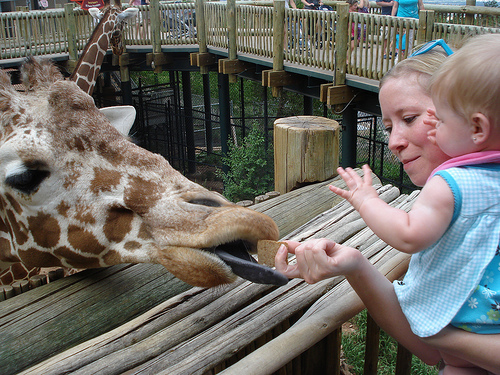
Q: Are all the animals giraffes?
A: Yes, all the animals are giraffes.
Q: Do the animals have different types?
A: No, all the animals are giraffes.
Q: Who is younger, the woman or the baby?
A: The baby is younger than the woman.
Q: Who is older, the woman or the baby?
A: The woman is older than the baby.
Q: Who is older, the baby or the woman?
A: The woman is older than the baby.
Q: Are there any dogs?
A: No, there are no dogs.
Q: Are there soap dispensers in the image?
A: No, there are no soap dispensers.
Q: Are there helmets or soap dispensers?
A: No, there are no soap dispensers or helmets.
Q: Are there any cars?
A: No, there are no cars.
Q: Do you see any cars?
A: No, there are no cars.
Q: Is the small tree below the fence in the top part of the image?
A: Yes, the tree is below the fence.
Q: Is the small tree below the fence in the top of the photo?
A: Yes, the tree is below the fence.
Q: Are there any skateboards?
A: No, there are no skateboards.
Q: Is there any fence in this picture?
A: Yes, there is a fence.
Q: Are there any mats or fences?
A: Yes, there is a fence.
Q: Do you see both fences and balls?
A: No, there is a fence but no balls.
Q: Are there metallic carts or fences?
A: Yes, there is a metal fence.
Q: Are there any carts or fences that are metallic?
A: Yes, the fence is metallic.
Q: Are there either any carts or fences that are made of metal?
A: Yes, the fence is made of metal.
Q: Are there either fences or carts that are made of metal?
A: Yes, the fence is made of metal.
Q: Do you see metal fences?
A: Yes, there is a fence that is made of metal.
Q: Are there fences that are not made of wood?
A: Yes, there is a fence that is made of metal.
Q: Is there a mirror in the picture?
A: No, there are no mirrors.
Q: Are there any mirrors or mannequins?
A: No, there are no mirrors or mannequins.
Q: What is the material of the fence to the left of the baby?
A: The fence is made of metal.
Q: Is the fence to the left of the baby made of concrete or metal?
A: The fence is made of metal.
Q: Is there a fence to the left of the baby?
A: Yes, there is a fence to the left of the baby.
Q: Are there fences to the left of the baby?
A: Yes, there is a fence to the left of the baby.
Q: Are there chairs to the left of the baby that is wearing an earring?
A: No, there is a fence to the left of the baby.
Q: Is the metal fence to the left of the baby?
A: Yes, the fence is to the left of the baby.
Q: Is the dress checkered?
A: Yes, the dress is checkered.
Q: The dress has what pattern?
A: The dress is checkered.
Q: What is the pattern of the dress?
A: The dress is checkered.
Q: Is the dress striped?
A: No, the dress is checkered.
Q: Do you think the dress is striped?
A: No, the dress is checkered.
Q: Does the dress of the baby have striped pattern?
A: No, the dress is checkered.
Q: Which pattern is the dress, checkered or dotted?
A: The dress is checkered.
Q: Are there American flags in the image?
A: No, there are no American flags.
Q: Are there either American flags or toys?
A: No, there are no American flags or toys.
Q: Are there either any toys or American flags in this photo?
A: No, there are no American flags or toys.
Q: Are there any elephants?
A: No, there are no elephants.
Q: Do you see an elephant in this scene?
A: No, there are no elephants.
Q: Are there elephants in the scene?
A: No, there are no elephants.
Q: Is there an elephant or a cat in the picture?
A: No, there are no elephants or cats.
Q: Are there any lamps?
A: No, there are no lamps.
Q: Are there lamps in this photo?
A: No, there are no lamps.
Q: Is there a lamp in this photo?
A: No, there are no lamps.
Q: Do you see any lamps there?
A: No, there are no lamps.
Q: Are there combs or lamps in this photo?
A: No, there are no lamps or combs.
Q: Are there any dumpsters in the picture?
A: No, there are no dumpsters.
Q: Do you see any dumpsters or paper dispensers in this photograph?
A: No, there are no dumpsters or paper dispensers.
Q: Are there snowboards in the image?
A: No, there are no snowboards.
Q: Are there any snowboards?
A: No, there are no snowboards.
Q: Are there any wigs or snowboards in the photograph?
A: No, there are no snowboards or wigs.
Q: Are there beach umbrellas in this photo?
A: No, there are no beach umbrellas.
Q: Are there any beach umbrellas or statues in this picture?
A: No, there are no beach umbrellas or statues.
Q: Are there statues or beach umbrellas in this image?
A: No, there are no beach umbrellas or statues.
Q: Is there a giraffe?
A: Yes, there are giraffes.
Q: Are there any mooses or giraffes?
A: Yes, there are giraffes.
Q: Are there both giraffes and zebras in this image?
A: No, there are giraffes but no zebras.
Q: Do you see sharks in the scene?
A: No, there are no sharks.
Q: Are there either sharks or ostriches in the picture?
A: No, there are no sharks or ostriches.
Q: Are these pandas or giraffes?
A: These are giraffes.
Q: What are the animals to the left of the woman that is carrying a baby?
A: The animals are giraffes.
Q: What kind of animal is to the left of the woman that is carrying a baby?
A: The animals are giraffes.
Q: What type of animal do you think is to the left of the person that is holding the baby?
A: The animals are giraffes.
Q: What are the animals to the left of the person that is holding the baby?
A: The animals are giraffes.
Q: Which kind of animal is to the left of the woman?
A: The animals are giraffes.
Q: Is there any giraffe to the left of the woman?
A: Yes, there are giraffes to the left of the woman.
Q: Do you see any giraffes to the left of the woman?
A: Yes, there are giraffes to the left of the woman.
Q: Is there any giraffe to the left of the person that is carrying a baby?
A: Yes, there are giraffes to the left of the woman.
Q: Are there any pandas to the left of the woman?
A: No, there are giraffes to the left of the woman.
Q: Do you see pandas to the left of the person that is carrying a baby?
A: No, there are giraffes to the left of the woman.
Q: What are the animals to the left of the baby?
A: The animals are giraffes.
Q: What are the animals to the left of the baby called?
A: The animals are giraffes.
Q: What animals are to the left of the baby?
A: The animals are giraffes.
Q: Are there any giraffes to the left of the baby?
A: Yes, there are giraffes to the left of the baby.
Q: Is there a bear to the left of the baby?
A: No, there are giraffes to the left of the baby.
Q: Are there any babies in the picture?
A: Yes, there is a baby.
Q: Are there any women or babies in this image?
A: Yes, there is a baby.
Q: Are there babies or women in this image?
A: Yes, there is a baby.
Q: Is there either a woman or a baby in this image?
A: Yes, there is a baby.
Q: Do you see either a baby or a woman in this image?
A: Yes, there is a baby.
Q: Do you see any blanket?
A: No, there are no blankets.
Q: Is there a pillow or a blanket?
A: No, there are no blankets or pillows.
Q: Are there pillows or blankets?
A: No, there are no blankets or pillows.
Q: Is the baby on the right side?
A: Yes, the baby is on the right of the image.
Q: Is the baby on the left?
A: No, the baby is on the right of the image.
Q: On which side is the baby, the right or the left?
A: The baby is on the right of the image.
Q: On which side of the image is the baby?
A: The baby is on the right of the image.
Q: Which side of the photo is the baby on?
A: The baby is on the right of the image.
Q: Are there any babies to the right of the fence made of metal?
A: Yes, there is a baby to the right of the fence.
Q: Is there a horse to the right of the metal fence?
A: No, there is a baby to the right of the fence.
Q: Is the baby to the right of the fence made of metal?
A: Yes, the baby is to the right of the fence.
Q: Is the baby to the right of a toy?
A: No, the baby is to the right of the fence.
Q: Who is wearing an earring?
A: The baby is wearing an earring.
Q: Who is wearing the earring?
A: The baby is wearing an earring.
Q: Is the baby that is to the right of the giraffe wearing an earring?
A: Yes, the baby is wearing an earring.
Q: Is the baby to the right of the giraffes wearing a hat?
A: No, the baby is wearing an earring.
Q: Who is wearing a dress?
A: The baby is wearing a dress.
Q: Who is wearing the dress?
A: The baby is wearing a dress.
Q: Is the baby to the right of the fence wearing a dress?
A: Yes, the baby is wearing a dress.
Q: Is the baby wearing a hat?
A: No, the baby is wearing a dress.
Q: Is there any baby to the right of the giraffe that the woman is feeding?
A: Yes, there is a baby to the right of the giraffe.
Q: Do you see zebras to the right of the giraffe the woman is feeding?
A: No, there is a baby to the right of the giraffe.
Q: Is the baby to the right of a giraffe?
A: Yes, the baby is to the right of a giraffe.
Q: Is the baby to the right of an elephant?
A: No, the baby is to the right of a giraffe.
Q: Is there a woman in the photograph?
A: Yes, there is a woman.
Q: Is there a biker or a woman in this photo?
A: Yes, there is a woman.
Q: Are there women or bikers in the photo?
A: Yes, there is a woman.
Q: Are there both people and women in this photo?
A: Yes, there are both a woman and people.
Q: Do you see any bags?
A: No, there are no bags.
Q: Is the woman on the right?
A: Yes, the woman is on the right of the image.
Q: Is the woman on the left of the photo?
A: No, the woman is on the right of the image.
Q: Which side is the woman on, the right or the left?
A: The woman is on the right of the image.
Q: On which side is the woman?
A: The woman is on the right of the image.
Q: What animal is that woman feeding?
A: The woman is feeding the giraffe.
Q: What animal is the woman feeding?
A: The woman is feeding the giraffe.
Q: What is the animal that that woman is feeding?
A: The animal is a giraffe.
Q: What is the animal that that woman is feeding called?
A: The animal is a giraffe.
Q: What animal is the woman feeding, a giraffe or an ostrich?
A: The woman is feeding a giraffe.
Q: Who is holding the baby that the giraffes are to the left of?
A: The woman is holding the baby.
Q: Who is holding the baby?
A: The woman is holding the baby.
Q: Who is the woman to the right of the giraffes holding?
A: The woman is holding the baby.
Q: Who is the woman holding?
A: The woman is holding the baby.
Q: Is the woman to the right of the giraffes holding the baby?
A: Yes, the woman is holding the baby.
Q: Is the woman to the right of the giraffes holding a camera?
A: No, the woman is holding the baby.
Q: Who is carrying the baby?
A: The woman is carrying the baby.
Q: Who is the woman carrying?
A: The woman is carrying a baby.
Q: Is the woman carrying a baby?
A: Yes, the woman is carrying a baby.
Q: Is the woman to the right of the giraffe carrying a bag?
A: No, the woman is carrying a baby.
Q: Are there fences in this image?
A: Yes, there is a fence.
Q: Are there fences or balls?
A: Yes, there is a fence.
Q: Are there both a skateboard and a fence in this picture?
A: No, there is a fence but no skateboards.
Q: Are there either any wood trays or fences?
A: Yes, there is a wood fence.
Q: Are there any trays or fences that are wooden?
A: Yes, the fence is wooden.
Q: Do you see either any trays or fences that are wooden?
A: Yes, the fence is wooden.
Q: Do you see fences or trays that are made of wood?
A: Yes, the fence is made of wood.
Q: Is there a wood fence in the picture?
A: Yes, there is a wood fence.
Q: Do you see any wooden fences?
A: Yes, there is a wood fence.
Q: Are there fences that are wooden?
A: Yes, there is a fence that is wooden.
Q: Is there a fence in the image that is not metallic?
A: Yes, there is a wooden fence.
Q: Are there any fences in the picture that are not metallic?
A: Yes, there is a wooden fence.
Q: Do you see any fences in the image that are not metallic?
A: Yes, there is a wooden fence.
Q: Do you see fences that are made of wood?
A: Yes, there is a fence that is made of wood.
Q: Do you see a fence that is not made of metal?
A: Yes, there is a fence that is made of wood.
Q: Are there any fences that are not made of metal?
A: Yes, there is a fence that is made of wood.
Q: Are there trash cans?
A: No, there are no trash cans.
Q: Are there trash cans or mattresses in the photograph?
A: No, there are no trash cans or mattresses.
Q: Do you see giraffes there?
A: Yes, there is a giraffe.